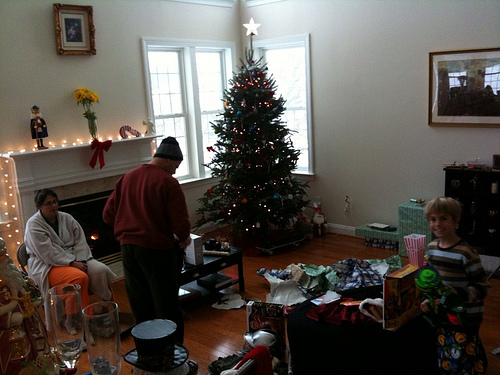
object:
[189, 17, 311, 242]
christmas tree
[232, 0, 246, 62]
corner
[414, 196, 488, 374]
boy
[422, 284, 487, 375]
pajamas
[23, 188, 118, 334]
woman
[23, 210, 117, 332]
robe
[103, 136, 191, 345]
man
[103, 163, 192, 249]
sweater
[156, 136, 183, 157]
hat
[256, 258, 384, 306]
wrapping paper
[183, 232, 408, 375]
floor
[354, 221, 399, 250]
present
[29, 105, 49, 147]
nutcracker doll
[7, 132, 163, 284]
fire place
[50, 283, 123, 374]
empty glasses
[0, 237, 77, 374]
corner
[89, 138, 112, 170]
red bow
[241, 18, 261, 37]
star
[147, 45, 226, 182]
window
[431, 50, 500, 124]
picture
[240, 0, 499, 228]
wall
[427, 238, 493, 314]
stripe shirt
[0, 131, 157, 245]
christmas lights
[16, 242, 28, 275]
chair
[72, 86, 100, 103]
flowers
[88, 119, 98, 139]
vase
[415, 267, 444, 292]
toy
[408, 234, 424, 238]
popcorn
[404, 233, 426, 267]
container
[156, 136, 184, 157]
ski cap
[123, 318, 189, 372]
top hat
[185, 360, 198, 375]
table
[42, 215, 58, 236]
sweater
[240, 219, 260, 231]
camera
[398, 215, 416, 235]
paper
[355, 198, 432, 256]
gifts